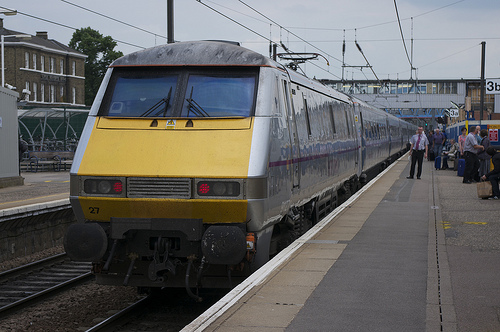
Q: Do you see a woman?
A: No, there are no women.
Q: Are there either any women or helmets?
A: No, there are no women or helmets.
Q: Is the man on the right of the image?
A: Yes, the man is on the right of the image.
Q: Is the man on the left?
A: No, the man is on the right of the image.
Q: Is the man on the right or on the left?
A: The man is on the right of the image.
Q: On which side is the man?
A: The man is on the right of the image.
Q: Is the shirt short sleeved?
A: Yes, the shirt is short sleeved.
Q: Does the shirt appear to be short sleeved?
A: Yes, the shirt is short sleeved.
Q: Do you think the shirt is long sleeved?
A: No, the shirt is short sleeved.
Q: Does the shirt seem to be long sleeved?
A: No, the shirt is short sleeved.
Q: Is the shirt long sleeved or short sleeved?
A: The shirt is short sleeved.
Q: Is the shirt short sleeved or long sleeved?
A: The shirt is short sleeved.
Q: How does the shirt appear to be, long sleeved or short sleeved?
A: The shirt is short sleeved.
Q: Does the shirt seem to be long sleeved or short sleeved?
A: The shirt is short sleeved.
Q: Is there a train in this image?
A: Yes, there is a train.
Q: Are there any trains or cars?
A: Yes, there is a train.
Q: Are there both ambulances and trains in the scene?
A: No, there is a train but no ambulances.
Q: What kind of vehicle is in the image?
A: The vehicle is a train.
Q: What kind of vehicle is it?
A: The vehicle is a train.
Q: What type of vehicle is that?
A: This is a train.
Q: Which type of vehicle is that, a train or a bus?
A: This is a train.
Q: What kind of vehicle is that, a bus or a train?
A: This is a train.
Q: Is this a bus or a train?
A: This is a train.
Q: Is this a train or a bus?
A: This is a train.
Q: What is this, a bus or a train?
A: This is a train.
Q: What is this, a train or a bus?
A: This is a train.